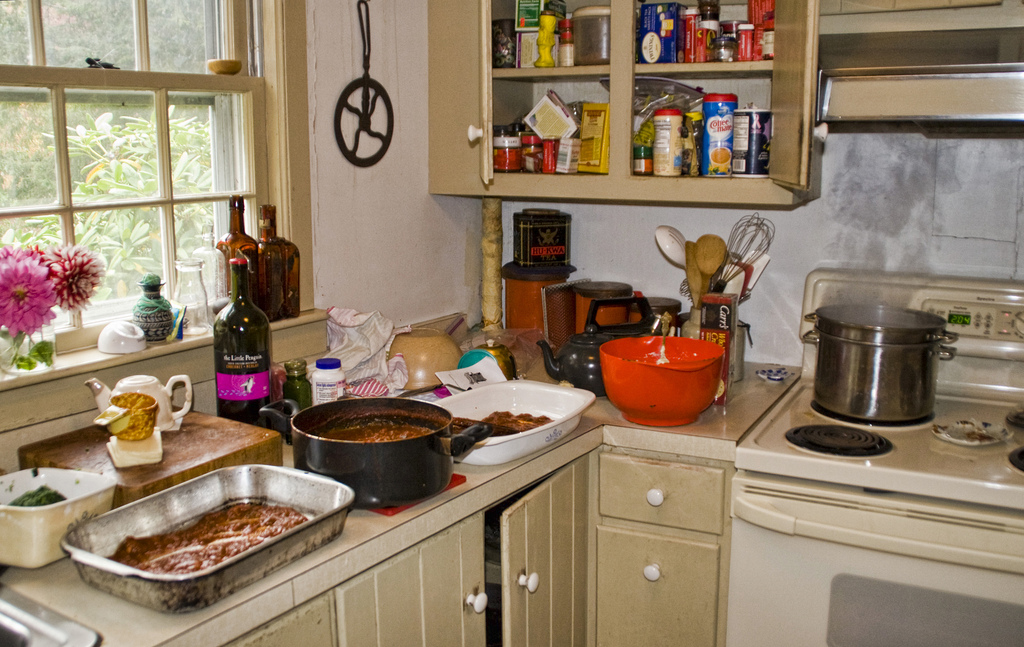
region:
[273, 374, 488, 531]
the pot has food in it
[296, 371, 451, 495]
the food id reddish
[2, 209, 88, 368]
flowers are on the window sil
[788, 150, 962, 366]
steam is coming out of the pot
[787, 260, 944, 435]
the pot is silver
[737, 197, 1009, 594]
the stove is white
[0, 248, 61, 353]
the flower is pink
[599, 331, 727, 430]
an orange bowl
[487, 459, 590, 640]
the cabinet open under the counter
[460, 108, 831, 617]
the knobs on the cabinet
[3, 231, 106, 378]
the flower in the window sill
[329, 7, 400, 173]
the art on the wall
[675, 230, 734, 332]
the wooden spoons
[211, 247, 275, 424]
the pink labeled bottle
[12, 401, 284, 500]
the cutting board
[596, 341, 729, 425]
a large red bowl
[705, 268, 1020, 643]
a white oven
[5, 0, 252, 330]
a kitchen window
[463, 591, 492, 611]
a white cabinet knob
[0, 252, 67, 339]
a large pink flower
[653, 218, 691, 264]
a white spoon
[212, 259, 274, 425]
a tall glass bottle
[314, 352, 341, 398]
a blue and white mayo container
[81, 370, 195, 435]
a small white teapot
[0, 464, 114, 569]
a white dish of food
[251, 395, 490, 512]
black pot full of red sauce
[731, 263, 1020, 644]
large pot boiling on white stove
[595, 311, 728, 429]
red bowl with silver utensil inside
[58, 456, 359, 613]
large silver pan with red sauce on bottom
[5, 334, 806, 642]
white countertop with beige drawers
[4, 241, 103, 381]
clear vase with pink and red flowers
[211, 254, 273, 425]
large bottle of wine with pink label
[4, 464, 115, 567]
beige container with green vegetables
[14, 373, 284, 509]
brown wooden block with white kettle on top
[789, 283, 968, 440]
A large silver pot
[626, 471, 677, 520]
A white knob on a drawer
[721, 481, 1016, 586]
A white oven door handle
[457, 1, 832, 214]
Many items in a cupboard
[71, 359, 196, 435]
A white tea kettle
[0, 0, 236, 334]
Trees outside a window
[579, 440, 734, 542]
A light brown wooden drawer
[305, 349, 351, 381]
Blue lid on a jar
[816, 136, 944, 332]
steam coming up from the pot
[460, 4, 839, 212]
cabinet doors are open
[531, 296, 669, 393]
teapot behind the bowl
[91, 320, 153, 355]
kitchen timer on the ledge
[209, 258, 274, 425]
wine bottle on the counter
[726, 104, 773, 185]
container of salt in the cabinet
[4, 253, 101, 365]
flowers on the ledge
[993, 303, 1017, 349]
lights on the stove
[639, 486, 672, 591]
handles on the cabinets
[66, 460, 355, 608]
sauce inside the pan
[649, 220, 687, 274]
a white cooking spoon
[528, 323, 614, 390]
a small black tea pot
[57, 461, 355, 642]
a long gray pan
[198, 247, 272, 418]
a tall wine bottle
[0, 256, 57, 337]
a large pink flower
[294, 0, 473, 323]
a white wall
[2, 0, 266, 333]
a kitchen window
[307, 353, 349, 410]
a blue and white tablet bottle